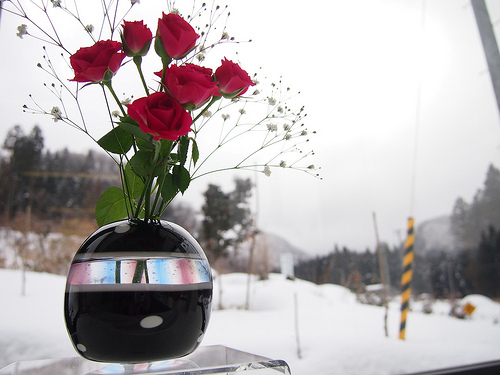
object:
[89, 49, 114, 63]
petal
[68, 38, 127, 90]
flower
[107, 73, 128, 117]
stem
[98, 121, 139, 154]
leaf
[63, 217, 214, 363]
vase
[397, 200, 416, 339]
pole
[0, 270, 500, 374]
snow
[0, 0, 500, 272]
sky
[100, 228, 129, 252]
light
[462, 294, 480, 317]
sign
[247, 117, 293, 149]
flower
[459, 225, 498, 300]
tree